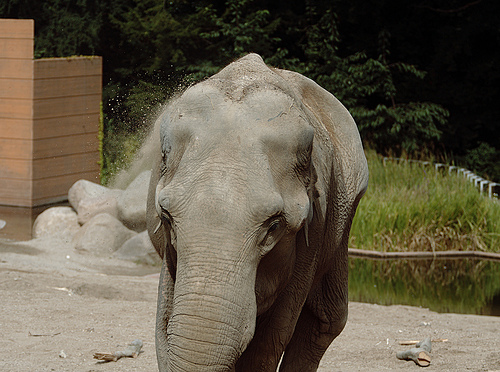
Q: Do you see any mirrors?
A: No, there are no mirrors.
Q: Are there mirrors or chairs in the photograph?
A: No, there are no mirrors or chairs.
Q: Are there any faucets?
A: No, there are no faucets.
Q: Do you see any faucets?
A: No, there are no faucets.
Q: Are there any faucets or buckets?
A: No, there are no faucets or buckets.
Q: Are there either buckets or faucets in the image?
A: No, there are no faucets or buckets.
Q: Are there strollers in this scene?
A: No, there are no strollers.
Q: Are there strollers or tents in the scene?
A: No, there are no strollers or tents.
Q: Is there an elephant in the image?
A: Yes, there is an elephant.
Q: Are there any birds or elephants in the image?
A: Yes, there is an elephant.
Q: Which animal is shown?
A: The animal is an elephant.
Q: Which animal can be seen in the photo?
A: The animal is an elephant.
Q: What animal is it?
A: The animal is an elephant.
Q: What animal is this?
A: That is an elephant.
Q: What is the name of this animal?
A: That is an elephant.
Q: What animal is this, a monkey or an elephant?
A: That is an elephant.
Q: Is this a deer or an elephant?
A: This is an elephant.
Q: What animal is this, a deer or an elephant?
A: This is an elephant.